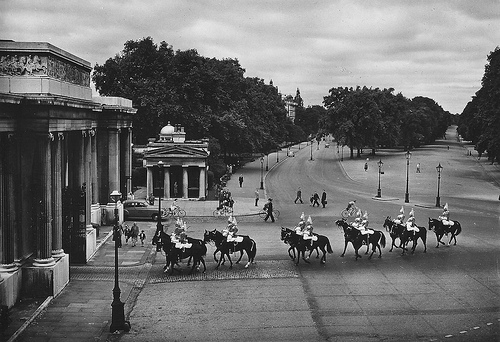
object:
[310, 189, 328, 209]
people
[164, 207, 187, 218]
bicycle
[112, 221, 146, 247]
family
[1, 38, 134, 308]
building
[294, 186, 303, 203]
person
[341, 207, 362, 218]
bicycle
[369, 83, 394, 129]
ground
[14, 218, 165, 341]
sidewalk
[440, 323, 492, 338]
dashes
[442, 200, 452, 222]
man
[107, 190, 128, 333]
lamp post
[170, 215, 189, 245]
man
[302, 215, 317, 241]
man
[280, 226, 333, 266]
horse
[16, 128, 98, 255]
pillars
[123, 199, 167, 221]
car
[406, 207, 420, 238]
man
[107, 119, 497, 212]
hill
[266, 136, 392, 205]
road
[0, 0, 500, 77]
cloud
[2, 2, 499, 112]
sky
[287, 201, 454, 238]
people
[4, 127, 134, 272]
columns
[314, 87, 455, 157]
bushes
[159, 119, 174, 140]
dome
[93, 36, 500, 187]
tree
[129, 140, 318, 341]
sidewalk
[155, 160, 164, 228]
light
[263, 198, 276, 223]
person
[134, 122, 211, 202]
building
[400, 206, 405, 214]
hats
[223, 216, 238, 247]
man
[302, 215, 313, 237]
man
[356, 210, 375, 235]
man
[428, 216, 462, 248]
horse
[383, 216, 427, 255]
horse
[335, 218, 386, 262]
horse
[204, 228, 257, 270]
horse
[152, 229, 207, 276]
horses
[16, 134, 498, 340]
street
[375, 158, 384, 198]
light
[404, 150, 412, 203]
light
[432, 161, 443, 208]
light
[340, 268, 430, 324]
road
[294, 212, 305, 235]
men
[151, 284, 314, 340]
pavement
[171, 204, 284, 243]
intersection